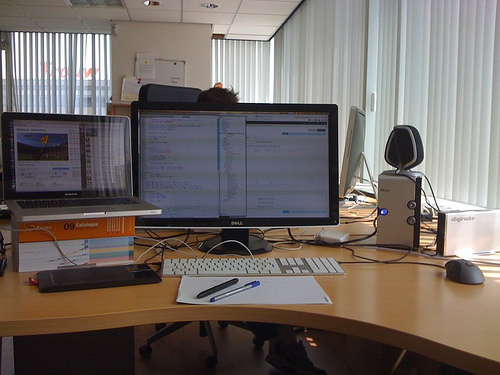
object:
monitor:
[135, 103, 339, 225]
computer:
[127, 103, 341, 256]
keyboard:
[162, 257, 347, 277]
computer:
[0, 112, 162, 223]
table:
[1, 202, 500, 368]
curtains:
[213, 36, 498, 207]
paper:
[176, 275, 334, 306]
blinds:
[3, 33, 114, 114]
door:
[3, 32, 112, 117]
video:
[17, 132, 70, 162]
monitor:
[3, 118, 126, 198]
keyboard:
[17, 196, 139, 209]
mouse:
[445, 258, 485, 284]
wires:
[135, 231, 255, 264]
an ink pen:
[196, 277, 260, 302]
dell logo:
[230, 220, 243, 225]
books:
[15, 217, 137, 275]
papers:
[121, 52, 156, 102]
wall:
[108, 22, 213, 98]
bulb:
[142, 1, 161, 8]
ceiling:
[3, 2, 303, 42]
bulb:
[205, 1, 219, 9]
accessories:
[35, 226, 485, 293]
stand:
[197, 228, 273, 255]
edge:
[7, 308, 184, 338]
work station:
[8, 82, 500, 374]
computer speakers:
[373, 124, 423, 251]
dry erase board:
[146, 58, 187, 88]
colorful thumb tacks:
[138, 78, 142, 84]